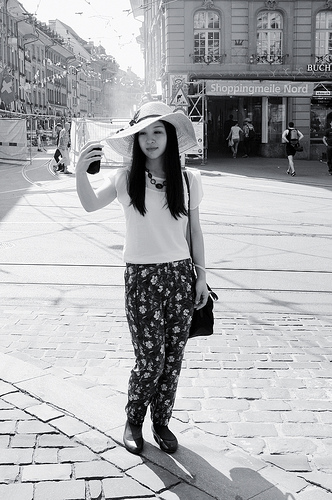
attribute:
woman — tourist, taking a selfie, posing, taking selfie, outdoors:
[76, 105, 211, 456]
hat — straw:
[105, 103, 197, 160]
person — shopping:
[227, 122, 242, 153]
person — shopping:
[242, 117, 258, 154]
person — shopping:
[281, 124, 304, 176]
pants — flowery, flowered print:
[125, 258, 196, 430]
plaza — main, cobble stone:
[3, 156, 331, 499]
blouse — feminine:
[119, 170, 198, 266]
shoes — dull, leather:
[124, 422, 177, 453]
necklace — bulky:
[146, 164, 168, 190]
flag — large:
[45, 44, 69, 109]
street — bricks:
[0, 312, 328, 497]